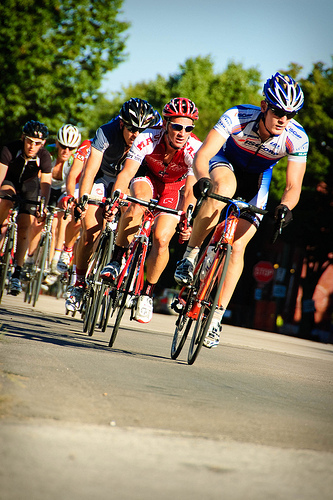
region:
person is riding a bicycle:
[205, 84, 295, 364]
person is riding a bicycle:
[130, 102, 201, 329]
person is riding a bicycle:
[83, 109, 143, 304]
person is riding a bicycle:
[51, 130, 74, 286]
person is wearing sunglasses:
[269, 93, 300, 121]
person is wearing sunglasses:
[171, 118, 199, 134]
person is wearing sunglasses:
[125, 124, 149, 135]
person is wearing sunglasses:
[60, 141, 75, 151]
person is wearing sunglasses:
[22, 134, 42, 146]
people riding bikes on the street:
[5, 73, 313, 348]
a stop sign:
[255, 261, 274, 281]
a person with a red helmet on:
[137, 94, 194, 254]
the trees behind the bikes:
[7, 22, 316, 129]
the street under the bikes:
[24, 324, 310, 481]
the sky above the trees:
[134, 8, 303, 56]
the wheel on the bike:
[199, 254, 218, 354]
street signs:
[271, 270, 287, 309]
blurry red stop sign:
[252, 260, 273, 282]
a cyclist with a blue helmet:
[168, 68, 309, 366]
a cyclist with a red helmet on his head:
[99, 97, 206, 347]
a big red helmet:
[161, 97, 200, 119]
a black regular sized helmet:
[118, 97, 155, 127]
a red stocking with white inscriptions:
[73, 266, 90, 286]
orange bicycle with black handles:
[171, 182, 286, 365]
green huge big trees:
[1, 0, 332, 202]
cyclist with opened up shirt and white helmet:
[30, 124, 80, 308]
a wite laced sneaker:
[135, 293, 153, 323]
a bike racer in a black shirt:
[0, 120, 52, 302]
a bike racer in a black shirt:
[73, 99, 156, 329]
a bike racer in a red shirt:
[100, 100, 204, 350]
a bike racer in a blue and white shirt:
[168, 72, 308, 365]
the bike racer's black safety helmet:
[19, 119, 48, 157]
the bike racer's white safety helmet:
[57, 126, 78, 161]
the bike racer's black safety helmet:
[116, 98, 156, 145]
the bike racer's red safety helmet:
[162, 96, 199, 149]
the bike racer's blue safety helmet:
[260, 72, 303, 135]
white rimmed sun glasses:
[167, 122, 196, 132]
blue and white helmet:
[264, 57, 295, 107]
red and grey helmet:
[159, 81, 198, 124]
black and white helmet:
[122, 96, 164, 124]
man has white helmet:
[51, 120, 88, 159]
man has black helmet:
[25, 109, 54, 145]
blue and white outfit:
[216, 97, 285, 209]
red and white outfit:
[130, 126, 190, 218]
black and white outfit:
[91, 106, 155, 218]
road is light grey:
[43, 380, 152, 471]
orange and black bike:
[184, 219, 254, 358]